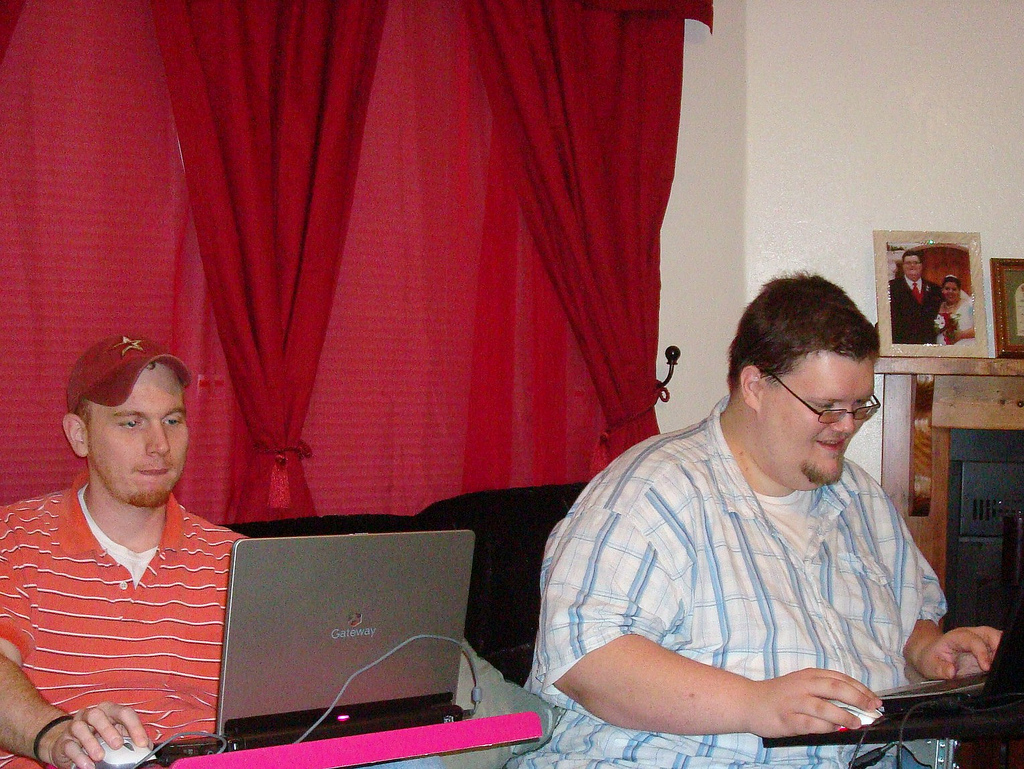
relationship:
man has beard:
[507, 270, 1000, 769] [801, 443, 856, 510]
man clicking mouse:
[8, 336, 237, 725] [75, 731, 155, 768]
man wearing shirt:
[8, 336, 237, 725] [11, 500, 238, 712]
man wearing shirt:
[507, 270, 1000, 769] [553, 474, 949, 762]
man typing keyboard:
[612, 279, 999, 766] [764, 661, 991, 765]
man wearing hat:
[0, 336, 247, 769] [49, 331, 164, 409]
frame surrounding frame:
[871, 223, 992, 370] [873, 230, 988, 358]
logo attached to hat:
[94, 335, 149, 370] [48, 318, 183, 407]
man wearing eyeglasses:
[507, 270, 1000, 769] [761, 371, 882, 424]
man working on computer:
[0, 336, 247, 769] [193, 515, 500, 742]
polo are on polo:
[0, 471, 249, 769] [20, 499, 237, 722]